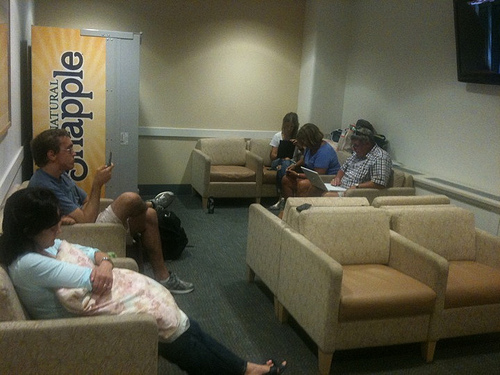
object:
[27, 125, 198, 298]
man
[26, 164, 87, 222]
shirt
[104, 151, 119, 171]
phone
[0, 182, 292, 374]
woman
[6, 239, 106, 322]
shirt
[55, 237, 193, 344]
pillow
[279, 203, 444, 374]
chair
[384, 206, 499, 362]
chair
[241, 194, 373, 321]
chair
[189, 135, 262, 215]
chair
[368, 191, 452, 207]
chair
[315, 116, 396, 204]
man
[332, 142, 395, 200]
shirt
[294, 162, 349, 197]
laptop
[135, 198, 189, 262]
backpack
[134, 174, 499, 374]
floor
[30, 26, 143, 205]
vending machine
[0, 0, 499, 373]
room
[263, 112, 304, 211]
person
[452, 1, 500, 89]
tv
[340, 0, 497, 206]
wall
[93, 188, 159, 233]
legs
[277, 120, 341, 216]
woman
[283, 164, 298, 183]
phone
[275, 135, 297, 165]
tablet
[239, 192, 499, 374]
group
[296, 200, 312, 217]
remote control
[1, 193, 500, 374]
carpet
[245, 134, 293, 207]
chair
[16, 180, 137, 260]
chair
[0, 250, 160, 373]
chair